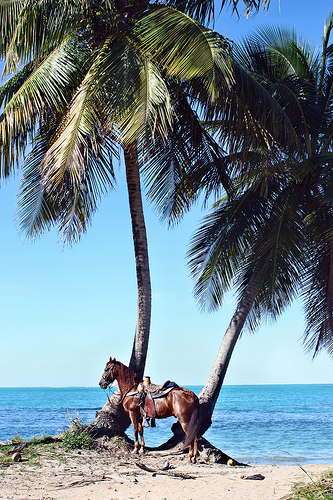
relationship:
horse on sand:
[98, 354, 203, 465] [95, 443, 165, 492]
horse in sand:
[98, 354, 203, 465] [95, 443, 165, 492]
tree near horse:
[39, 17, 238, 298] [98, 354, 203, 465]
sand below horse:
[95, 443, 165, 492] [98, 354, 203, 465]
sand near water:
[95, 443, 165, 492] [243, 382, 302, 485]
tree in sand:
[39, 17, 238, 298] [95, 443, 165, 492]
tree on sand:
[39, 17, 238, 298] [95, 443, 165, 492]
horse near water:
[98, 354, 203, 465] [243, 382, 302, 485]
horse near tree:
[98, 354, 203, 465] [39, 17, 238, 298]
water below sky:
[243, 382, 302, 485] [21, 247, 162, 372]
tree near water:
[39, 17, 238, 298] [243, 382, 302, 485]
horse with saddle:
[98, 354, 199, 453] [138, 380, 171, 396]